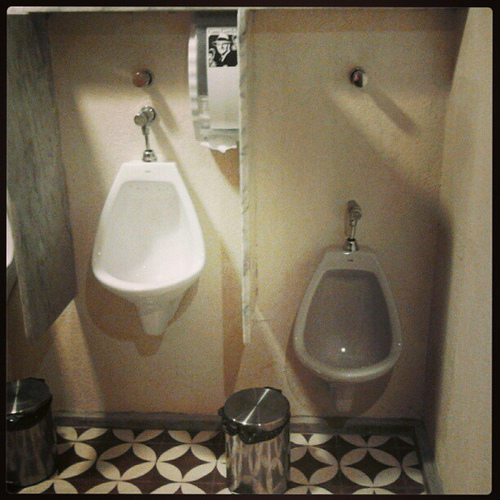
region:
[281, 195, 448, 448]
A low to the ground urinal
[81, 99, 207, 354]
A white porcelain urinal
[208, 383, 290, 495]
A small silver garbage can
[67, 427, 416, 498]
A maroon and white tiled floor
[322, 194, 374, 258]
Silver colored urinal flush button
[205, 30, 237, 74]
Small black and white picture of man in hat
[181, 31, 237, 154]
White plastic toilet paper dispenser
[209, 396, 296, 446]
Small black garbage bag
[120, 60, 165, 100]
Chrome urinal flush button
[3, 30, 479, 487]
this is a bathroom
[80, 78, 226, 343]
this is urinal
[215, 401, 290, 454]
black lining of trash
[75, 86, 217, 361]
the urinal is white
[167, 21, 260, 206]
dispenser above the urinal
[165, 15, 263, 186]
the dispenser is white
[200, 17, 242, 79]
black face on dispenser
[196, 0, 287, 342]
stall wall in bathroom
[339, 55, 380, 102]
silver flush button on wall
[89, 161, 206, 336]
a white porcelain urinal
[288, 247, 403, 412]
a light grey unrinal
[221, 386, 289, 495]
a brushed aluminum trash can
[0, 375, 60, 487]
a brushed aluminum trash can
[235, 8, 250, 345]
a urinal partition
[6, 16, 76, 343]
a urinal partition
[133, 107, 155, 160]
a chrome flush valve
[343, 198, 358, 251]
a chrome flush valve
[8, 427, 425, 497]
brown and white tiled bathroom floor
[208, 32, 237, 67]
drawing of man's face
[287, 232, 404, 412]
urinal in bathroom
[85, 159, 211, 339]
urinal in bathroom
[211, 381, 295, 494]
silver trash can in bathroom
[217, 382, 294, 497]
a bathroom garbage can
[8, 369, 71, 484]
a bathroom garbage can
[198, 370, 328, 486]
a silver garbage can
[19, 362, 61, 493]
a silver garbage can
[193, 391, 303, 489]
a black garbage bag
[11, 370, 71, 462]
a black garbage bag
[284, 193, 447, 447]
a urinal on the wall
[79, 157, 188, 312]
a urinal on the wall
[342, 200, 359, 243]
a silver pipe on the wall